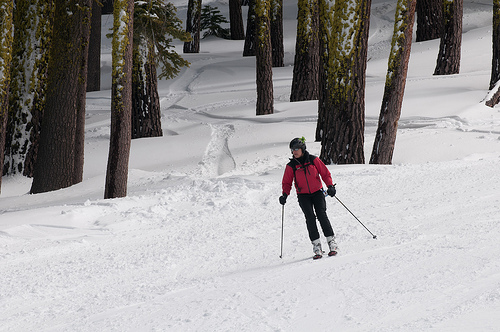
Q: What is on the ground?
A: Snow.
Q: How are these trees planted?
A: Very close to each other.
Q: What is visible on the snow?
A: Ski marks.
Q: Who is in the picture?
A: Skier.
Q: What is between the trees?
A: A ski trail.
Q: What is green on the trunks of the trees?
A: Moss.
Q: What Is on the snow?
A: The trail.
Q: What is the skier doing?
A: Going downhill.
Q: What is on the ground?
A: Snow.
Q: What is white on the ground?
A: Snow.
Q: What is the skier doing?
A: Skiing downhill.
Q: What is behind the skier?
A: A large tree.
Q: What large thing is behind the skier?
A: A tree.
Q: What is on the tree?
A: Snow.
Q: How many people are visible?
A: One.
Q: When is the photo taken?
A: Daytime.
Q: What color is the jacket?
A: Red.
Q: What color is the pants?
A: Black.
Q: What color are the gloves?
A: Black.